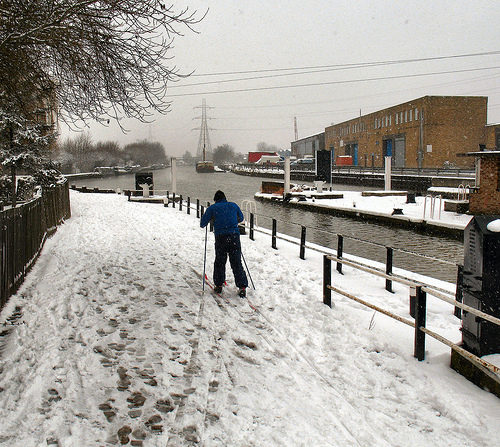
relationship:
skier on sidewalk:
[199, 189, 258, 300] [2, 182, 497, 446]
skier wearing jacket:
[199, 189, 258, 300] [200, 202, 243, 234]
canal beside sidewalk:
[68, 149, 465, 287] [2, 182, 497, 446]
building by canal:
[322, 94, 486, 175] [68, 149, 465, 287]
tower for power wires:
[187, 91, 221, 164] [123, 50, 500, 102]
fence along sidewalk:
[0, 175, 73, 301] [2, 182, 497, 446]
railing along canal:
[227, 161, 477, 184] [68, 149, 465, 287]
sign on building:
[424, 142, 435, 157] [322, 94, 486, 175]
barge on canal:
[193, 158, 217, 175] [68, 149, 465, 287]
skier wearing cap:
[199, 189, 258, 300] [211, 189, 229, 204]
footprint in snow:
[116, 424, 133, 444] [2, 184, 493, 441]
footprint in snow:
[148, 412, 165, 434] [2, 184, 493, 441]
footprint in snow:
[126, 394, 145, 422] [2, 184, 493, 441]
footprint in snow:
[46, 386, 64, 405] [2, 184, 493, 441]